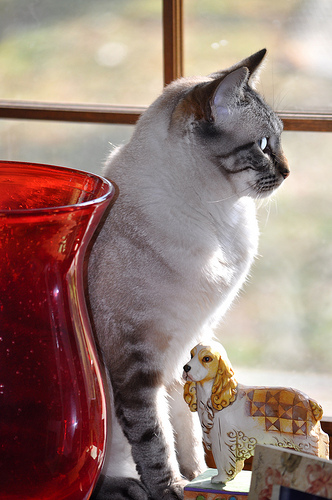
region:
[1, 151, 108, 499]
Large red glass vase.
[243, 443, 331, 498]
Picture frame with flower designs.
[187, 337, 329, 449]
Porcelain dog.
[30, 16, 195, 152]
Window pane and window frame.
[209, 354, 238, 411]
Golden ears on porcelain dog.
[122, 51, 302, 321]
Cat sitting beside window.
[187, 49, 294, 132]
Cat's grey and white ears.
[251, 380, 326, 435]
Design on porcelain dog's back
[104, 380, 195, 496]
Grey and while cat paws.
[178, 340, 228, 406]
Procelain dog's white and gold face.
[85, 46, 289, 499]
white and light brown striped cat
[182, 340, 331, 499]
dog figurine on window ledge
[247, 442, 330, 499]
upper left corner of picture frame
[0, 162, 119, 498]
red glass vase in front of cat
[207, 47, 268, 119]
pointed ears of cat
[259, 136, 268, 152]
light green glowing eyes on cat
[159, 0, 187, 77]
wood frame on window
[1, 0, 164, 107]
glass on window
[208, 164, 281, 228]
whiskers on cat's face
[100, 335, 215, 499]
front legs of cat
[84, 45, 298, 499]
white and grey cat by window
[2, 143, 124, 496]
red vase by a window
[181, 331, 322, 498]
ceramic dog decoration by a window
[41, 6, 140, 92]
glass of a wincow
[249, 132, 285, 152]
right eye of a cat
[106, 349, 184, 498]
right front leg of a cat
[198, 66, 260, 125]
right ear of a cat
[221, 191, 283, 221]
whiskers of a cat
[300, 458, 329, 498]
pink flower on a frame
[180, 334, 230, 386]
face of a ceramic dog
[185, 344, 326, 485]
small dog porcelain figurine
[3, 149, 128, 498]
a red vase next to a cat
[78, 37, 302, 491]
cat sits on a table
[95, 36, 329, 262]
cat sits facing right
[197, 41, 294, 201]
cat has pointy ears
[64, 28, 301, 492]
cat is brown, white and black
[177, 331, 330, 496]
a toy ornament next to cat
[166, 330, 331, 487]
dog ornament is yellow and white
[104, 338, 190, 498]
leg of cat has brown stripes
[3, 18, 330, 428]
a cat is in front a window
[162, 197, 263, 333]
chest of cat is white